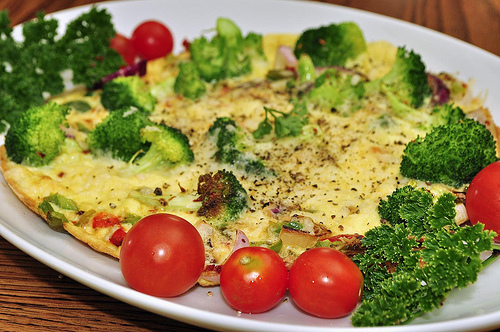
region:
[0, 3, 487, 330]
white plate with food on it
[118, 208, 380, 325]
three tomatoes in the foreground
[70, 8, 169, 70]
two tomatoes in the background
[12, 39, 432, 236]
broccoli pieces in the omelet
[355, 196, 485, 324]
piece of broccoli next to three tomatoes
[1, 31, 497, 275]
omelet on white plate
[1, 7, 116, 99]
broccoli on back edge of plate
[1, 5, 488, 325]
wood table white plate is on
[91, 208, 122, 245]
tomato chunk in omelet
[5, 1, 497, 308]
tomatoes and broccoli on white plate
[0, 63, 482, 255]
a pizza on a plate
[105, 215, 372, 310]
three cherry tomatoes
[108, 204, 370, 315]
three tomatoes on a plate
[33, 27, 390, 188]
pieces of broccoli on a pizza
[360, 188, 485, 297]
a piece of parsley on a plate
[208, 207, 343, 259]
chopped onions on a pizza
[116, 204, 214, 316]
a cherry tomato on a plate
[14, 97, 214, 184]
broccoli on a plate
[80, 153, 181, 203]
melted cheese on a pizza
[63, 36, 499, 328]
a pizza on a white plate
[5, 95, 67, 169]
Bright green broccoli on the omelet.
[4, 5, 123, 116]
Fresh green parsley on the plate.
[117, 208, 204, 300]
Bright red cherry tomato.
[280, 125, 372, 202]
Seasoning on the omelet.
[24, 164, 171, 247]
Part of an omelet.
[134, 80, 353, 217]
Eggs are great for breakfast.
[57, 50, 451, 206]
The meal was prepared in a cafe.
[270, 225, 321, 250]
Bit of onion on the omelet.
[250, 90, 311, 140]
Some parsley on the egg for color.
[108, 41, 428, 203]
The egg looks very tasty.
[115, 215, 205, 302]
The large tomato on the lower left.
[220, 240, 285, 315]
The small tomato in the middle on the bottom.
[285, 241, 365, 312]
The tomato on the right on the bottom.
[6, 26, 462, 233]
The pieces of broccoli on the pizza.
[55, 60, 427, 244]
The melted cheese on the pizza.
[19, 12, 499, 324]
The plate the food is placed on.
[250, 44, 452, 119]
The purple pieces of ham on the pizza.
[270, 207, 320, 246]
The piece of onion above the bottom row of tomatoes.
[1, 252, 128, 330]
The left corner of the table.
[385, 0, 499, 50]
The right corner of the table.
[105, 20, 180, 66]
The tomatoes at the top of the plate.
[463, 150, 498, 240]
The tomato on the right side of the plate.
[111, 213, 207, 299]
The tomato on the left in the row on the bottom.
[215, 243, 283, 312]
The tomato in the middle of the row.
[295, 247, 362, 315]
The tomato on the right of the row.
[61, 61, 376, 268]
The pieces of ham on the pizza.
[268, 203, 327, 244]
The piece of onion above the row of tomatoes.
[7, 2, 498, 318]
The white plate the pizza and vegetables are placed on.